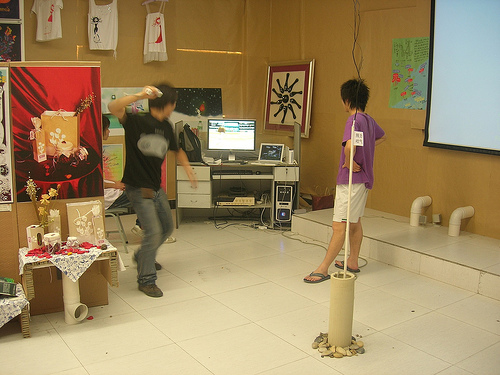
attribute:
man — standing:
[299, 77, 393, 288]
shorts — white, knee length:
[327, 183, 373, 226]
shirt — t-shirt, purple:
[334, 111, 387, 191]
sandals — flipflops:
[293, 257, 363, 290]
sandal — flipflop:
[332, 256, 362, 276]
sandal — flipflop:
[301, 266, 334, 287]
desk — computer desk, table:
[171, 145, 304, 234]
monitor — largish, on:
[200, 117, 259, 165]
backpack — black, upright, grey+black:
[177, 118, 215, 167]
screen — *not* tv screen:
[207, 118, 257, 154]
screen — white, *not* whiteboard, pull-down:
[418, 1, 499, 156]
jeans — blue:
[123, 179, 177, 283]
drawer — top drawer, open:
[175, 164, 213, 184]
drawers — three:
[174, 164, 214, 209]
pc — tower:
[274, 182, 294, 226]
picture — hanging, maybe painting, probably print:
[260, 57, 318, 140]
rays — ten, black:
[270, 72, 303, 124]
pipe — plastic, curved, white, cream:
[445, 204, 477, 241]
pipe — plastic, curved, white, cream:
[406, 193, 435, 229]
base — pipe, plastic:
[54, 262, 93, 328]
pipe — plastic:
[57, 259, 93, 327]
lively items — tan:
[20, 171, 115, 265]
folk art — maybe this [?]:
[307, 2, 375, 372]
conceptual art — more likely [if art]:
[308, 2, 370, 364]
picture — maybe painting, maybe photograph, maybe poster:
[11, 65, 105, 201]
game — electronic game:
[202, 116, 297, 230]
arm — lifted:
[104, 84, 166, 124]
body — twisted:
[123, 107, 178, 276]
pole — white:
[341, 117, 357, 276]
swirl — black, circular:
[267, 73, 303, 125]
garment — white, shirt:
[135, 1, 172, 74]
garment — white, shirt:
[80, 0, 124, 63]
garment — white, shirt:
[29, 1, 69, 48]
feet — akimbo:
[300, 254, 364, 286]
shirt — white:
[105, 141, 125, 214]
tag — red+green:
[339, 217, 349, 225]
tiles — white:
[0, 219, 500, 374]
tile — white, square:
[207, 279, 321, 323]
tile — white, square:
[136, 292, 252, 340]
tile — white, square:
[170, 320, 310, 374]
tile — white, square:
[53, 310, 173, 365]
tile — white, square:
[378, 308, 499, 366]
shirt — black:
[118, 109, 185, 193]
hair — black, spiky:
[338, 75, 375, 114]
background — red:
[9, 68, 103, 199]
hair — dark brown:
[147, 78, 179, 116]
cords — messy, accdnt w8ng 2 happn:
[211, 148, 370, 273]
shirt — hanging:
[138, 0, 172, 69]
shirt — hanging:
[82, 0, 122, 62]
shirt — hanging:
[26, 0, 69, 45]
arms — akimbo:
[340, 112, 390, 179]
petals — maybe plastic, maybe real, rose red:
[23, 235, 103, 262]